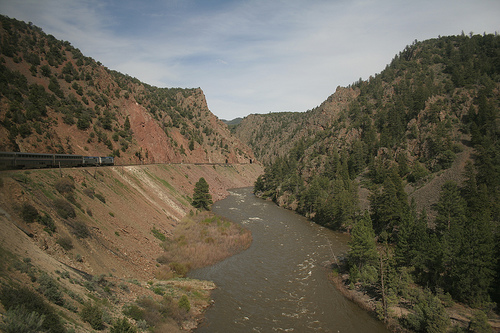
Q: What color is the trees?
A: Green.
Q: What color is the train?
A: Grey.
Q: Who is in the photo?
A: Nobody.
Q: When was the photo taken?
A: During the day.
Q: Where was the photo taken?
A: In a river gorge.